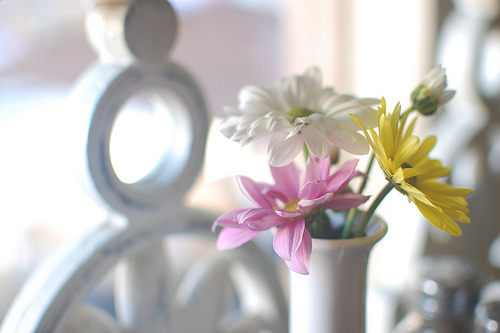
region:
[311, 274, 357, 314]
a white flower vase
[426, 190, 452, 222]
yellow petals of a flower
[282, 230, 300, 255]
pink petals of a flower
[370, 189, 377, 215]
the stalk of the flower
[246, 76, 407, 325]
a vase with flowers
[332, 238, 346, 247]
the rim of a flower vase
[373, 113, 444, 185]
a fresh yellow flower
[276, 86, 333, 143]
a white fresh flower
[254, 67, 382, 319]
fresh flowers in a vase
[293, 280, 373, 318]
the neck of a flower vase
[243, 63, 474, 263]
flowers in the flower vase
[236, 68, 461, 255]
different colors of flowers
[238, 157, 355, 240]
pink color flower with green stem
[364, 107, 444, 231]
yellow color flower with green stem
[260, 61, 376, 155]
white color flower in the vase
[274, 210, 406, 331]
white color flower vase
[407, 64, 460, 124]
bud of the white color flower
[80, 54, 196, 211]
circle shape of the design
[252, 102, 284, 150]
white color petals of the flower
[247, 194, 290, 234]
pink color petals of the flower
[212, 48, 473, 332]
flowers in a white vase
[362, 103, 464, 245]
yellow flower in vase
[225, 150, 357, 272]
pink flower in vase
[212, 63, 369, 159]
white flower in vase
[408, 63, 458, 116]
white flower that hasn't bloomed yet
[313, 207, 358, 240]
shadow of flowers inside vase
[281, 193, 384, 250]
lip of the white vase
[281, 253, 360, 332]
neck of the white vase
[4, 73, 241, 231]
sqaure of sunlight in the background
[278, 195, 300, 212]
yellow center of purple flower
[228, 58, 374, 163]
White flower in vase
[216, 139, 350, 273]
Pink flower in vase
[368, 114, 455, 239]
Yellow flower in vase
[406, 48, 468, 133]
White flower half bloomed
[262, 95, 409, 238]
Flowers with green stems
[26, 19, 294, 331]
White decoration in background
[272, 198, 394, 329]
White ceramic vase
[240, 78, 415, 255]
Four flowers in vase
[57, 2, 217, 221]
Circle decoration in background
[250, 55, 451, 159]
Two white flowers in vase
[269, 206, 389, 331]
a white vase holding flowers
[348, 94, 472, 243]
a yellow flower with a green stem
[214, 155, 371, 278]
a pink flower with a yellow center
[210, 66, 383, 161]
a white flower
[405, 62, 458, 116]
a white flower with it's pedals closed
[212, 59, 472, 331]
a small bouquet of flowers in a white vase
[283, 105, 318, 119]
the yellow center of a white flower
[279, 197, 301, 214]
the yellow center of a pink flower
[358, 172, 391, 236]
green stem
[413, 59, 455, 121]
this flower does not look healthy